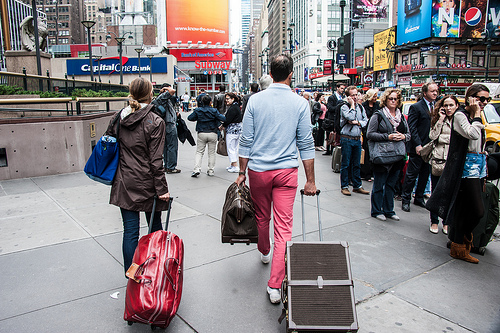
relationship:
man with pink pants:
[228, 44, 333, 313] [243, 160, 293, 301]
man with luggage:
[235, 54, 317, 304] [220, 182, 259, 246]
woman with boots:
[427, 82, 492, 263] [447, 232, 479, 264]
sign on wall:
[66, 55, 168, 75] [51, 52, 176, 84]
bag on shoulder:
[84, 108, 125, 186] [113, 102, 126, 127]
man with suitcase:
[235, 54, 317, 304] [218, 180, 262, 248]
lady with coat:
[108, 74, 198, 259] [99, 91, 191, 198]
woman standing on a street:
[424, 84, 488, 264] [0, 112, 497, 332]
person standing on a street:
[366, 87, 410, 221] [0, 112, 497, 332]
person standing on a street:
[400, 80, 437, 212] [0, 112, 497, 332]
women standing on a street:
[418, 95, 460, 235] [0, 112, 497, 332]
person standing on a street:
[338, 82, 369, 194] [0, 112, 497, 332]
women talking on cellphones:
[426, 85, 498, 262] [468, 92, 481, 104]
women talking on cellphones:
[418, 95, 460, 235] [438, 105, 446, 115]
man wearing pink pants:
[235, 54, 317, 304] [249, 168, 298, 289]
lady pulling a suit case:
[104, 78, 172, 280] [124, 196, 185, 331]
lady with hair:
[104, 78, 172, 280] [127, 75, 153, 115]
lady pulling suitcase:
[104, 78, 172, 280] [272, 166, 359, 331]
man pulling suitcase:
[235, 54, 317, 304] [132, 192, 179, 329]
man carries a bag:
[235, 54, 317, 304] [225, 177, 296, 247]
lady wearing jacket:
[104, 78, 172, 280] [104, 99, 234, 196]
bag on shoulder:
[87, 125, 123, 187] [106, 110, 135, 136]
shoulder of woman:
[106, 110, 135, 136] [90, 74, 175, 277]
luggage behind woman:
[123, 229, 198, 330] [90, 79, 189, 275]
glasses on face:
[479, 96, 493, 103] [474, 89, 484, 106]